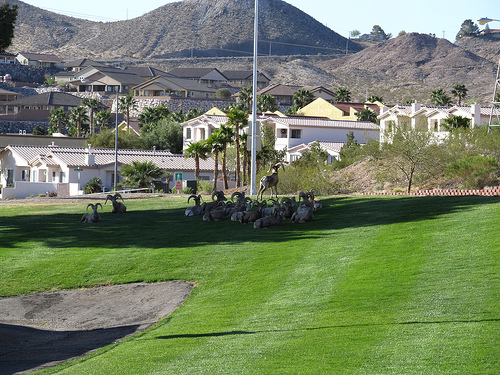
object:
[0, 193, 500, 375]
golf course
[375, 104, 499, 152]
house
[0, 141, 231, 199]
house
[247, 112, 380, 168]
house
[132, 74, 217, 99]
house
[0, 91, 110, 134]
house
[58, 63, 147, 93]
houses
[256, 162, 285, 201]
animals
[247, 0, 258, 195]
pole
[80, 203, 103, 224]
animal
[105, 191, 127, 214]
animal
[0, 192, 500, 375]
grass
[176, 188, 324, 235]
animals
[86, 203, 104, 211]
horns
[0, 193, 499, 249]
shade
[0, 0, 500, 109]
view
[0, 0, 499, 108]
mountain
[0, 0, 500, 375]
field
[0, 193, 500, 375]
ground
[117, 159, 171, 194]
palm bushes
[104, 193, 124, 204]
corner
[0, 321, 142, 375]
shadow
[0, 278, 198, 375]
road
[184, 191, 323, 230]
animals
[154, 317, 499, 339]
line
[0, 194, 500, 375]
grass field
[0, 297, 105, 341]
sand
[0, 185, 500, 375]
yard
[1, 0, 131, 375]
left